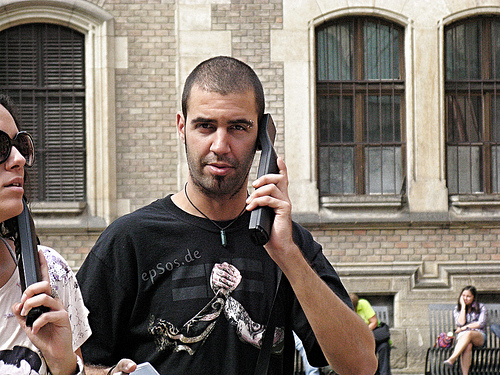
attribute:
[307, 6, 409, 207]
window — very large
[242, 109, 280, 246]
phone — large, black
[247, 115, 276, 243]
phone — black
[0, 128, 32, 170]
sunglasses — dark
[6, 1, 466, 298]
building — large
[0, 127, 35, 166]
sunglasses — black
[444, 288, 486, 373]
woman — sitting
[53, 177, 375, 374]
shirt — short sleeve, black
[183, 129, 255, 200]
facial hair — patchy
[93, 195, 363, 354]
tshirt — black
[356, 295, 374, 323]
shirt — short sleeve, yellow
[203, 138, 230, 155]
nose — shiny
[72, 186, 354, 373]
shirt — black